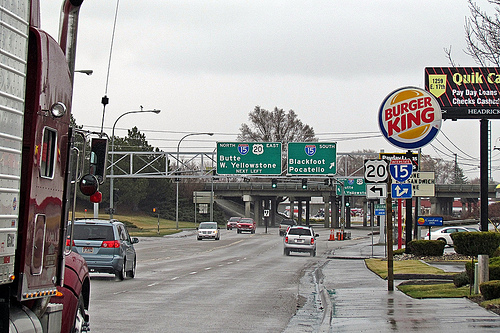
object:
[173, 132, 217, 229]
street light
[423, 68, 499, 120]
billboard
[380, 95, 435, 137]
burger king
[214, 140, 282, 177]
street sign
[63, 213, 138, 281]
car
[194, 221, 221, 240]
car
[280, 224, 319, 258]
car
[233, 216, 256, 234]
car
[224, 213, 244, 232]
car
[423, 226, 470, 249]
car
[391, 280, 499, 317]
grass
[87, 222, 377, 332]
road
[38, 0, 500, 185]
sky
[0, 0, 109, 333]
trailer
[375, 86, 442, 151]
sign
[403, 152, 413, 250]
pole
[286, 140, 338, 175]
sign